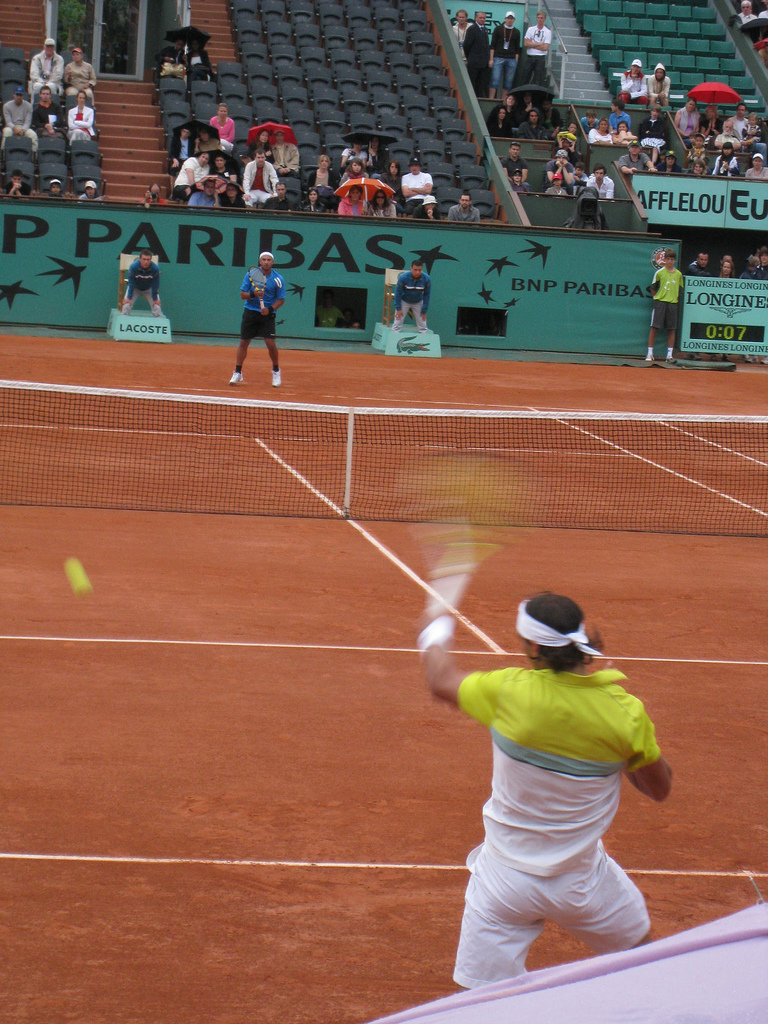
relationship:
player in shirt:
[414, 588, 682, 1005] [450, 659, 659, 879]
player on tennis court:
[414, 588, 682, 1005] [3, 342, 741, 1022]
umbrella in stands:
[682, 75, 744, 130] [567, 2, 744, 187]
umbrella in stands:
[327, 174, 398, 206] [150, 8, 506, 223]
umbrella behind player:
[327, 174, 398, 206] [217, 247, 299, 390]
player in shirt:
[217, 247, 299, 390] [239, 268, 286, 315]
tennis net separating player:
[0, 374, 745, 537] [222, 247, 297, 393]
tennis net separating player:
[0, 374, 745, 537] [414, 587, 682, 1005]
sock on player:
[232, 363, 243, 374] [222, 247, 296, 394]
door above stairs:
[47, 0, 188, 83] [93, 76, 176, 204]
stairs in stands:
[93, 76, 176, 204] [5, 2, 506, 222]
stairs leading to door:
[93, 76, 176, 204] [47, 0, 188, 83]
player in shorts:
[217, 247, 299, 390] [241, 308, 285, 341]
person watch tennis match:
[613, 53, 652, 108] [113, 182, 699, 977]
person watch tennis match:
[644, 53, 674, 111] [186, 226, 699, 988]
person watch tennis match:
[582, 159, 621, 209] [186, 226, 699, 988]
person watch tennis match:
[537, 143, 578, 187] [163, 212, 738, 966]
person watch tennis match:
[490, 134, 529, 181] [186, 226, 699, 988]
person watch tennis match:
[669, 98, 710, 153] [186, 226, 699, 988]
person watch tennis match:
[616, 115, 638, 162] [186, 226, 699, 988]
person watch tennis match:
[241, 137, 280, 209] [186, 226, 699, 988]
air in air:
[30, 493, 161, 610] [29, 486, 160, 656]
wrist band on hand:
[409, 612, 462, 651] [412, 592, 456, 625]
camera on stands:
[568, 187, 609, 228] [537, 170, 640, 231]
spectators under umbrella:
[336, 182, 397, 215] [334, 173, 395, 195]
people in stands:
[468, 3, 562, 106] [462, 9, 635, 145]